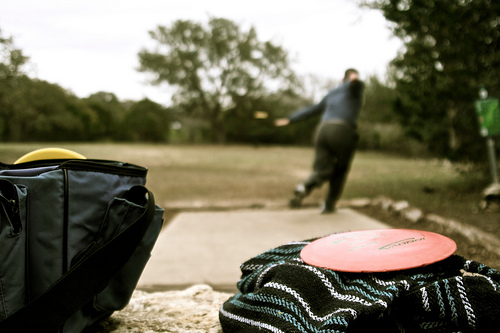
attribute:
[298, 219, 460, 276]
frisbee — red, orange, lying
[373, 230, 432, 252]
lettering — black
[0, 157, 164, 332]
bag — black, grey, dark gray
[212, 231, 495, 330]
pullover — striped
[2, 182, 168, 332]
strap — black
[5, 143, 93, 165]
frisbee — yellow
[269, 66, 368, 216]
man — running, tossing, playing, throwing, practicing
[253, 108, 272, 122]
frisbee — yellow, tossed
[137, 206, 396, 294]
slab — cement, tan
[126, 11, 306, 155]
tree — faded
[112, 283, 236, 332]
rock — tan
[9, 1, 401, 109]
sky — gray, faded, cloudy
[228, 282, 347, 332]
stripes — blue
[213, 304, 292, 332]
stripe — white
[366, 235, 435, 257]
writing — black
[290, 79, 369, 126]
shirt — blue, worn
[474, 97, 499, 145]
sign — green, nearby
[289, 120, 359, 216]
trouser — brown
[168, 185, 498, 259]
line — white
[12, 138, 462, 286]
sporting equipment — disk shaped